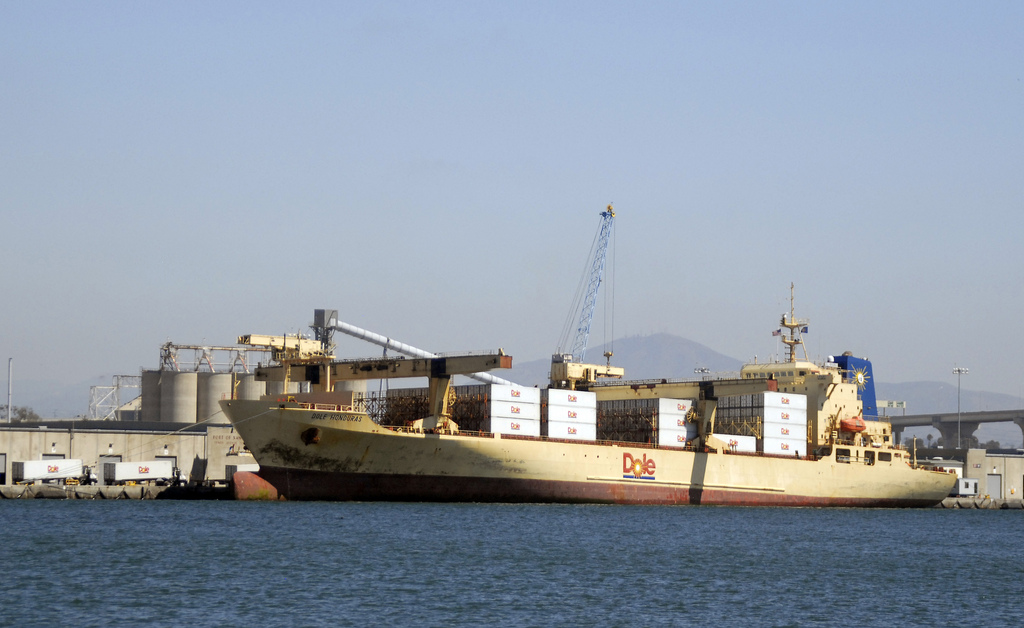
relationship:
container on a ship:
[548, 389, 597, 409] [209, 392, 955, 513]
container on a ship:
[744, 386, 812, 407] [212, 391, 958, 537]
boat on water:
[198, 379, 967, 525] [4, 468, 1022, 623]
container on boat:
[721, 389, 808, 408] [215, 359, 965, 534]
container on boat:
[548, 389, 597, 409] [212, 388, 958, 535]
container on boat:
[485, 376, 540, 405] [217, 373, 964, 513]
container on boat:
[213, 376, 972, 516] [216, 392, 962, 548]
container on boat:
[545, 379, 599, 409] [217, 394, 961, 522]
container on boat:
[212, 382, 963, 525] [210, 386, 954, 513]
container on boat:
[490, 385, 540, 404] [198, 379, 967, 525]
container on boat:
[485, 376, 544, 402] [213, 376, 960, 503]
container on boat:
[212, 382, 963, 525] [217, 373, 964, 513]